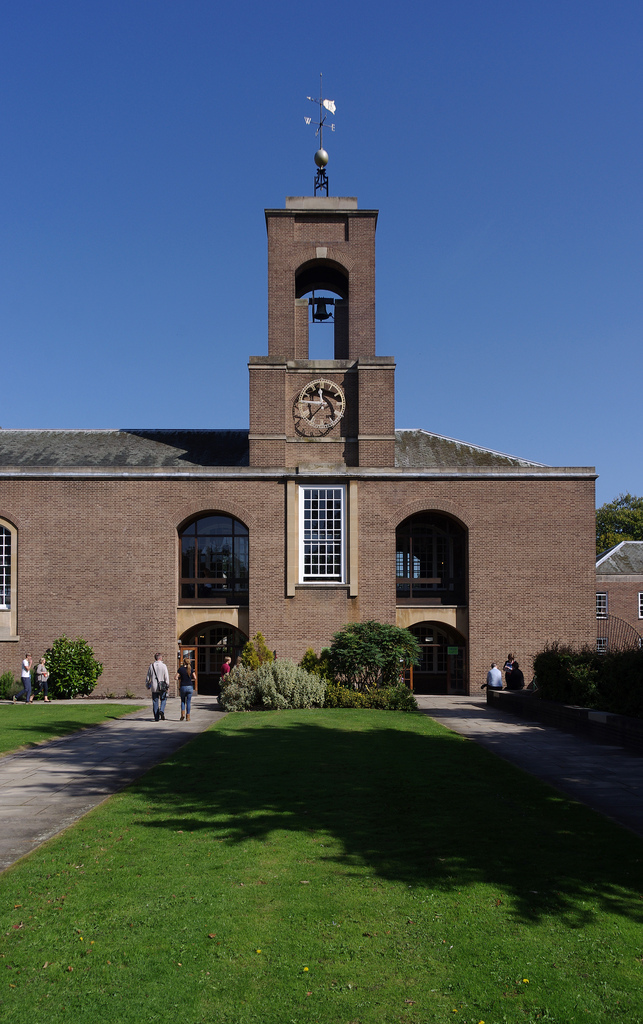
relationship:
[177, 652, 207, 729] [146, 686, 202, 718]
woman wearing denim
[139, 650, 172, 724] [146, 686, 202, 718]
man wearing denim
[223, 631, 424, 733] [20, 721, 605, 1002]
tree on grass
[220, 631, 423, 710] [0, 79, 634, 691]
landscaping in front of building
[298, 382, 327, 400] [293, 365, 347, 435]
hands on clock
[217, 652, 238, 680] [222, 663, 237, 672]
person wearing shirt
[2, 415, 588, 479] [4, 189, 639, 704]
roof on building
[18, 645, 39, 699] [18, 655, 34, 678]
person wearing shirt